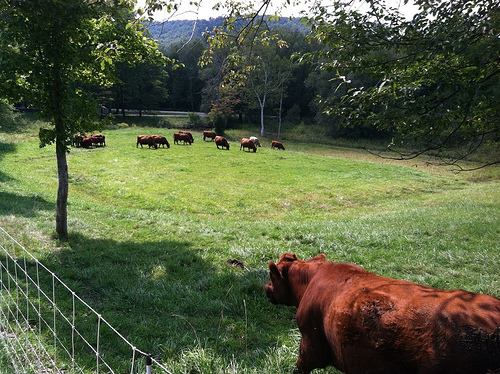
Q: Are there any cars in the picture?
A: No, there are no cars.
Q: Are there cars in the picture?
A: No, there are no cars.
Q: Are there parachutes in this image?
A: No, there are no parachutes.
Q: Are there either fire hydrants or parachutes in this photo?
A: No, there are no parachutes or fire hydrants.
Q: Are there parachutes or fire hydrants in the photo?
A: No, there are no parachutes or fire hydrants.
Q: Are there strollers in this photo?
A: No, there are no strollers.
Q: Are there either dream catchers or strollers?
A: No, there are no strollers or dream catchers.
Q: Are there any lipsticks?
A: No, there are no lipsticks.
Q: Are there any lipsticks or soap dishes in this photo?
A: No, there are no lipsticks or soap dishes.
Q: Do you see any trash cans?
A: No, there are no trash cans.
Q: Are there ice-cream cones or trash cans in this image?
A: No, there are no trash cans or ice-cream cones.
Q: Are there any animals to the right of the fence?
A: Yes, there is an animal to the right of the fence.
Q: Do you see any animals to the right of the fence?
A: Yes, there is an animal to the right of the fence.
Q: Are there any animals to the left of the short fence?
A: No, the animal is to the right of the fence.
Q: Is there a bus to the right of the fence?
A: No, there is an animal to the right of the fence.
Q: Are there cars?
A: No, there are no cars.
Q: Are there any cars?
A: No, there are no cars.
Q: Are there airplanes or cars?
A: No, there are no cars or airplanes.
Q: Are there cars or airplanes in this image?
A: No, there are no cars or airplanes.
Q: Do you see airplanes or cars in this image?
A: No, there are no cars or airplanes.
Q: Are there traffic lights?
A: No, there are no traffic lights.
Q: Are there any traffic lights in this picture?
A: No, there are no traffic lights.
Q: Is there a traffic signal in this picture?
A: No, there are no traffic lights.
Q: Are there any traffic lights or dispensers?
A: No, there are no traffic lights or dispensers.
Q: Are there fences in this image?
A: Yes, there is a fence.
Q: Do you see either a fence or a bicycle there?
A: Yes, there is a fence.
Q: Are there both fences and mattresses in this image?
A: No, there is a fence but no mattresses.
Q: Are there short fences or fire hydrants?
A: Yes, there is a short fence.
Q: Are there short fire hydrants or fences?
A: Yes, there is a short fence.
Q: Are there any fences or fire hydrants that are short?
A: Yes, the fence is short.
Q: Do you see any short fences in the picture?
A: Yes, there is a short fence.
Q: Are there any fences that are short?
A: Yes, there is a fence that is short.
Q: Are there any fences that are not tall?
A: Yes, there is a short fence.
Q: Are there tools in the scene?
A: No, there are no tools.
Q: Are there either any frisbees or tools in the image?
A: No, there are no tools or frisbees.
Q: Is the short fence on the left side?
A: Yes, the fence is on the left of the image.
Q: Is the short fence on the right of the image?
A: No, the fence is on the left of the image.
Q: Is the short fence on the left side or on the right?
A: The fence is on the left of the image.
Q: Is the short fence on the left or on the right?
A: The fence is on the left of the image.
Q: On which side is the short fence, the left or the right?
A: The fence is on the left of the image.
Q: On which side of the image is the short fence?
A: The fence is on the left of the image.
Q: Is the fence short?
A: Yes, the fence is short.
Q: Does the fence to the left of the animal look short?
A: Yes, the fence is short.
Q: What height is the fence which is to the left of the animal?
A: The fence is short.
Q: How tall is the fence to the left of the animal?
A: The fence is short.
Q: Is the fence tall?
A: No, the fence is short.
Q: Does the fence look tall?
A: No, the fence is short.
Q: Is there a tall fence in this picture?
A: No, there is a fence but it is short.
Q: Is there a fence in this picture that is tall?
A: No, there is a fence but it is short.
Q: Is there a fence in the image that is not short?
A: No, there is a fence but it is short.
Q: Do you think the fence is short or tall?
A: The fence is short.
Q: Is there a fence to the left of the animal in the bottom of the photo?
A: Yes, there is a fence to the left of the animal.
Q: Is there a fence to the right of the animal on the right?
A: No, the fence is to the left of the animal.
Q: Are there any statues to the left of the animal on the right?
A: No, there is a fence to the left of the animal.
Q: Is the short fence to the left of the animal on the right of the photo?
A: Yes, the fence is to the left of the animal.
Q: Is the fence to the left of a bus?
A: No, the fence is to the left of the animal.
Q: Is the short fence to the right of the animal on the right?
A: No, the fence is to the left of the animal.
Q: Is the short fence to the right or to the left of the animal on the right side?
A: The fence is to the left of the animal.